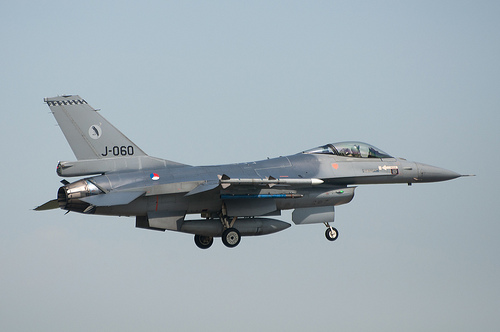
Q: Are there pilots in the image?
A: Yes, there is a pilot.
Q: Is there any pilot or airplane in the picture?
A: Yes, there is a pilot.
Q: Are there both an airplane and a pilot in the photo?
A: Yes, there are both a pilot and an airplane.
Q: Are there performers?
A: No, there are no performers.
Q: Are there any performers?
A: No, there are no performers.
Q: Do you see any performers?
A: No, there are no performers.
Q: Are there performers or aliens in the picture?
A: No, there are no performers or aliens.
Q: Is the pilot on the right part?
A: Yes, the pilot is on the right of the image.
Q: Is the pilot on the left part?
A: No, the pilot is on the right of the image.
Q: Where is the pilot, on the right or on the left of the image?
A: The pilot is on the right of the image.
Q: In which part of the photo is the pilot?
A: The pilot is on the right of the image.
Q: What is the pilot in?
A: The pilot is in the airplane.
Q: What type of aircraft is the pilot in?
A: The pilot is in the plane.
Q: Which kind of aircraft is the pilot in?
A: The pilot is in the plane.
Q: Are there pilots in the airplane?
A: Yes, there is a pilot in the airplane.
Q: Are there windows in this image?
A: Yes, there is a window.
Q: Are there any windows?
A: Yes, there is a window.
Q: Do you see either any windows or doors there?
A: Yes, there is a window.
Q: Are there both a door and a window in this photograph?
A: No, there is a window but no doors.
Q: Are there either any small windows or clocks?
A: Yes, there is a small window.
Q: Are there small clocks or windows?
A: Yes, there is a small window.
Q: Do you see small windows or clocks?
A: Yes, there is a small window.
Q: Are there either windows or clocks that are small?
A: Yes, the window is small.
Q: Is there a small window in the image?
A: Yes, there is a small window.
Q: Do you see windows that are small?
A: Yes, there is a window that is small.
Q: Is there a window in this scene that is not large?
A: Yes, there is a small window.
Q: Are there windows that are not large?
A: Yes, there is a small window.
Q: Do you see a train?
A: No, there are no trains.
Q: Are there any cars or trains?
A: No, there are no trains or cars.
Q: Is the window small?
A: Yes, the window is small.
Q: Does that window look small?
A: Yes, the window is small.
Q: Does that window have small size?
A: Yes, the window is small.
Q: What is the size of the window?
A: The window is small.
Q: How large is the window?
A: The window is small.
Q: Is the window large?
A: No, the window is small.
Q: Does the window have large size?
A: No, the window is small.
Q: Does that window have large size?
A: No, the window is small.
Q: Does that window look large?
A: No, the window is small.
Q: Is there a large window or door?
A: No, there is a window but it is small.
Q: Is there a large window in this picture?
A: No, there is a window but it is small.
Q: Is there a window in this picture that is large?
A: No, there is a window but it is small.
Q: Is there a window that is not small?
A: No, there is a window but it is small.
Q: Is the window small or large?
A: The window is small.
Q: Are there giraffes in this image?
A: No, there are no giraffes.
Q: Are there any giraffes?
A: No, there are no giraffes.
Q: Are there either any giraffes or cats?
A: No, there are no giraffes or cats.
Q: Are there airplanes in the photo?
A: Yes, there is an airplane.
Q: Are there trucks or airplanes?
A: Yes, there is an airplane.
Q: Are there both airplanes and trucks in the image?
A: No, there is an airplane but no trucks.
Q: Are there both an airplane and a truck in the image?
A: No, there is an airplane but no trucks.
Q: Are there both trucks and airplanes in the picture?
A: No, there is an airplane but no trucks.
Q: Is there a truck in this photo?
A: No, there are no trucks.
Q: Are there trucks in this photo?
A: No, there are no trucks.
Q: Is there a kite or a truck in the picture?
A: No, there are no trucks or kites.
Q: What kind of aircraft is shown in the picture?
A: The aircraft is an airplane.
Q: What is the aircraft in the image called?
A: The aircraft is an airplane.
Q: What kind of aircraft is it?
A: The aircraft is an airplane.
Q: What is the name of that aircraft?
A: This is an airplane.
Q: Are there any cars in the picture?
A: No, there are no cars.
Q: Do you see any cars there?
A: No, there are no cars.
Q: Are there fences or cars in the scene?
A: No, there are no cars or fences.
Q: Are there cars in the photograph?
A: No, there are no cars.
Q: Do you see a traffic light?
A: No, there are no traffic lights.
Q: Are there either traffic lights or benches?
A: No, there are no traffic lights or benches.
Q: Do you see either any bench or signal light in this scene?
A: No, there are no traffic lights or benches.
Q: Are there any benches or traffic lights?
A: No, there are no traffic lights or benches.